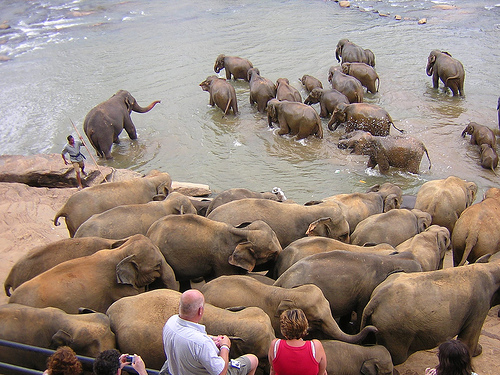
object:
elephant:
[82, 89, 161, 160]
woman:
[265, 307, 328, 375]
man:
[60, 134, 88, 191]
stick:
[68, 116, 108, 184]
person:
[92, 348, 149, 375]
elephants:
[50, 168, 173, 238]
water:
[0, 1, 497, 210]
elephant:
[336, 129, 431, 175]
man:
[161, 288, 259, 375]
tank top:
[271, 338, 321, 374]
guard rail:
[0, 338, 58, 374]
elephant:
[424, 48, 465, 97]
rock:
[418, 18, 427, 24]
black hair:
[92, 348, 121, 374]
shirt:
[162, 313, 225, 374]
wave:
[17, 21, 80, 34]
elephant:
[199, 75, 239, 118]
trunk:
[133, 100, 160, 114]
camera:
[125, 355, 134, 363]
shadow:
[99, 137, 145, 169]